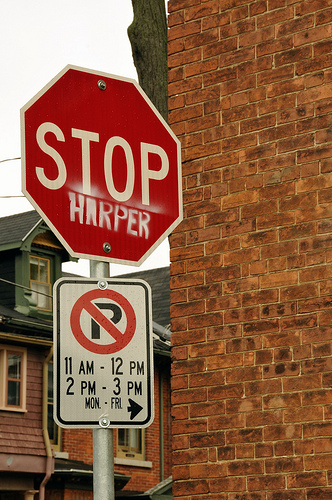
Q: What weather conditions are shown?
A: It is clear.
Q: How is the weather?
A: It is clear.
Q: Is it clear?
A: Yes, it is clear.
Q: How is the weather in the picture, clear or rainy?
A: It is clear.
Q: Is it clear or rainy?
A: It is clear.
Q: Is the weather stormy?
A: No, it is clear.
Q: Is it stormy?
A: No, it is clear.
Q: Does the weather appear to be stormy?
A: No, it is clear.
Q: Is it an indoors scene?
A: Yes, it is indoors.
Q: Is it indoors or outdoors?
A: It is indoors.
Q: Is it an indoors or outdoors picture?
A: It is indoors.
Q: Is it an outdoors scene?
A: No, it is indoors.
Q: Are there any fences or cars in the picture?
A: No, there are no cars or fences.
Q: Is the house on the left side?
A: Yes, the house is on the left of the image.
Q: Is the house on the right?
A: No, the house is on the left of the image.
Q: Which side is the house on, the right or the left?
A: The house is on the left of the image.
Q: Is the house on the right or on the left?
A: The house is on the left of the image.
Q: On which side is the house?
A: The house is on the left of the image.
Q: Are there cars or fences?
A: No, there are no cars or fences.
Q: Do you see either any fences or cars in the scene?
A: No, there are no cars or fences.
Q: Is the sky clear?
A: Yes, the sky is clear.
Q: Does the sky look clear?
A: Yes, the sky is clear.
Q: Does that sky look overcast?
A: No, the sky is clear.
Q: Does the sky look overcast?
A: No, the sky is clear.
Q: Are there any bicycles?
A: No, there are no bicycles.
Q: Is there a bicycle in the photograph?
A: No, there are no bicycles.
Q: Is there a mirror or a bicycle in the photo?
A: No, there are no bicycles or mirrors.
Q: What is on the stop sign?
A: The graffiti is on the stop sign.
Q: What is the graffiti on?
A: The graffiti is on the stop sign.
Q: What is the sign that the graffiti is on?
A: The sign is a stop sign.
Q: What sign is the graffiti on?
A: The graffiti is on the stop sign.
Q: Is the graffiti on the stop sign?
A: Yes, the graffiti is on the stop sign.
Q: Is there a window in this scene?
A: Yes, there is a window.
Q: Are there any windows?
A: Yes, there is a window.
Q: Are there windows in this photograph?
A: Yes, there is a window.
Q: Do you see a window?
A: Yes, there is a window.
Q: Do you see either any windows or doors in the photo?
A: Yes, there is a window.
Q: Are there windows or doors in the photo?
A: Yes, there is a window.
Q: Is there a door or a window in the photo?
A: Yes, there is a window.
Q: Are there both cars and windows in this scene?
A: No, there is a window but no cars.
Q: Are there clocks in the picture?
A: No, there are no clocks.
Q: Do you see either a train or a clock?
A: No, there are no clocks or trains.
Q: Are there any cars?
A: No, there are no cars.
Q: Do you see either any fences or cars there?
A: No, there are no cars or fences.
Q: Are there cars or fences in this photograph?
A: No, there are no cars or fences.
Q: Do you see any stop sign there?
A: Yes, there is a stop sign.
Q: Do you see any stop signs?
A: Yes, there is a stop sign.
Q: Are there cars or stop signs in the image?
A: Yes, there is a stop sign.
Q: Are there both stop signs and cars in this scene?
A: No, there is a stop sign but no cars.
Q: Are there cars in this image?
A: No, there are no cars.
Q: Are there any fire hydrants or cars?
A: No, there are no cars or fire hydrants.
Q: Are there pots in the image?
A: No, there are no pots.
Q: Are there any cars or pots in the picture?
A: No, there are no pots or cars.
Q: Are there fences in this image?
A: No, there are no fences.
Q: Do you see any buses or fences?
A: No, there are no fences or buses.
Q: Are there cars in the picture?
A: No, there are no cars.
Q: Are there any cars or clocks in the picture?
A: No, there are no cars or clocks.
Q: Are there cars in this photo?
A: No, there are no cars.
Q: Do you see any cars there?
A: No, there are no cars.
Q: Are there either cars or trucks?
A: No, there are no cars or trucks.